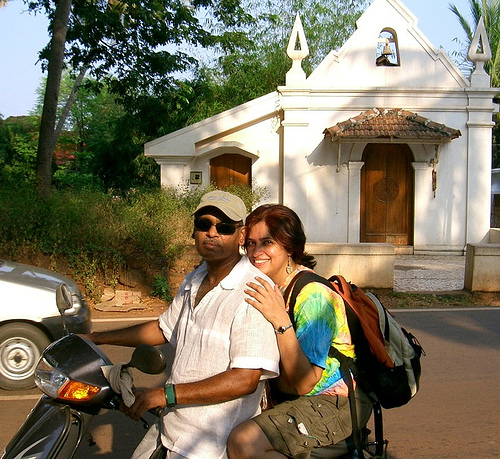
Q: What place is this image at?
A: It is at the church.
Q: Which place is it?
A: It is a church.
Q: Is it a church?
A: Yes, it is a church.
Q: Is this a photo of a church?
A: Yes, it is showing a church.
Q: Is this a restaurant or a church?
A: It is a church.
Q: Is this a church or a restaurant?
A: It is a church.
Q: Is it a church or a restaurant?
A: It is a church.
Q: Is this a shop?
A: No, it is a church.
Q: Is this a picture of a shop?
A: No, the picture is showing a church.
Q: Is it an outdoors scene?
A: Yes, it is outdoors.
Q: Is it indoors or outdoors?
A: It is outdoors.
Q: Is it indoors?
A: No, it is outdoors.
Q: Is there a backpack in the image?
A: Yes, there is a backpack.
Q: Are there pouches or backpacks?
A: Yes, there is a backpack.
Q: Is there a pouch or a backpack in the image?
A: Yes, there is a backpack.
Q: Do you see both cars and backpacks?
A: Yes, there are both a backpack and a car.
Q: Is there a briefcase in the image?
A: No, there are no briefcases.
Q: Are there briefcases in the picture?
A: No, there are no briefcases.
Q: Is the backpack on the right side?
A: Yes, the backpack is on the right of the image.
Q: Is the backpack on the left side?
A: No, the backpack is on the right of the image.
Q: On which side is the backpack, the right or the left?
A: The backpack is on the right of the image.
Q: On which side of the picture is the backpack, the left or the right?
A: The backpack is on the right of the image.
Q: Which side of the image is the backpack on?
A: The backpack is on the right of the image.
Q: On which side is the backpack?
A: The backpack is on the right of the image.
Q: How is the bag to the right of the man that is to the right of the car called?
A: The bag is a backpack.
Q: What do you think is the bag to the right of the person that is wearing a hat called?
A: The bag is a backpack.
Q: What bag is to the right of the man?
A: The bag is a backpack.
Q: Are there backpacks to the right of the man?
A: Yes, there is a backpack to the right of the man.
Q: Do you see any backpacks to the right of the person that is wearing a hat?
A: Yes, there is a backpack to the right of the man.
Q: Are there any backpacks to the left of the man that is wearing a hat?
A: No, the backpack is to the right of the man.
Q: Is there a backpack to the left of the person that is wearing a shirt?
A: No, the backpack is to the right of the man.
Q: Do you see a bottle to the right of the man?
A: No, there is a backpack to the right of the man.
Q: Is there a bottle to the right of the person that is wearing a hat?
A: No, there is a backpack to the right of the man.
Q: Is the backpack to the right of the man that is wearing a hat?
A: Yes, the backpack is to the right of the man.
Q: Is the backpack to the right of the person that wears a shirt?
A: Yes, the backpack is to the right of the man.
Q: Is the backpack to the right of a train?
A: No, the backpack is to the right of the man.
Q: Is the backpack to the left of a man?
A: No, the backpack is to the right of a man.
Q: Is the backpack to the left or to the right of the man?
A: The backpack is to the right of the man.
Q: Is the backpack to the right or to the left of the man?
A: The backpack is to the right of the man.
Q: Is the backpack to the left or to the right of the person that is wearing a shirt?
A: The backpack is to the right of the man.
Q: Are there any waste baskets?
A: No, there are no waste baskets.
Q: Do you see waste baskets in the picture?
A: No, there are no waste baskets.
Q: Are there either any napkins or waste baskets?
A: No, there are no waste baskets or napkins.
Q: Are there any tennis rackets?
A: No, there are no tennis rackets.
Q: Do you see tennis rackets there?
A: No, there are no tennis rackets.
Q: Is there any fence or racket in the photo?
A: No, there are no rackets or fences.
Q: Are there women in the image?
A: Yes, there is a woman.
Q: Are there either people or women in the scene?
A: Yes, there is a woman.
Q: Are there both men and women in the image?
A: Yes, there are both a woman and a man.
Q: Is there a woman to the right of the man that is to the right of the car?
A: Yes, there is a woman to the right of the man.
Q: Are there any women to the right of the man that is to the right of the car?
A: Yes, there is a woman to the right of the man.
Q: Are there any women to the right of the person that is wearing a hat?
A: Yes, there is a woman to the right of the man.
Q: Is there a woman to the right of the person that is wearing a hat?
A: Yes, there is a woman to the right of the man.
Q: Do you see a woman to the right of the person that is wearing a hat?
A: Yes, there is a woman to the right of the man.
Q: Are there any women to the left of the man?
A: No, the woman is to the right of the man.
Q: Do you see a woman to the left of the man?
A: No, the woman is to the right of the man.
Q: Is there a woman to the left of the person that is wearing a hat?
A: No, the woman is to the right of the man.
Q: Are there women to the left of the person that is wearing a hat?
A: No, the woman is to the right of the man.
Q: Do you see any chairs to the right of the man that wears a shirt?
A: No, there is a woman to the right of the man.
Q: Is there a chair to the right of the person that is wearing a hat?
A: No, there is a woman to the right of the man.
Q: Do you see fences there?
A: No, there are no fences.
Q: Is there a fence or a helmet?
A: No, there are no fences or helmets.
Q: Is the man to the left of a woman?
A: Yes, the man is to the left of a woman.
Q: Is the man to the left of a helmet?
A: No, the man is to the left of a woman.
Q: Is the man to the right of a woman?
A: No, the man is to the left of a woman.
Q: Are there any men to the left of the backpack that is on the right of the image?
A: Yes, there is a man to the left of the backpack.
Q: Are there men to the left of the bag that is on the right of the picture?
A: Yes, there is a man to the left of the backpack.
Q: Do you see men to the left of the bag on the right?
A: Yes, there is a man to the left of the backpack.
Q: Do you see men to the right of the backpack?
A: No, the man is to the left of the backpack.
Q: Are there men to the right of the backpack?
A: No, the man is to the left of the backpack.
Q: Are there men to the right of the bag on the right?
A: No, the man is to the left of the backpack.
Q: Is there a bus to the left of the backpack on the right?
A: No, there is a man to the left of the backpack.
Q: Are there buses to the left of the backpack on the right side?
A: No, there is a man to the left of the backpack.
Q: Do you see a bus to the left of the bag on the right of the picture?
A: No, there is a man to the left of the backpack.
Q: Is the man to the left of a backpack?
A: Yes, the man is to the left of a backpack.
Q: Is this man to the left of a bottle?
A: No, the man is to the left of a backpack.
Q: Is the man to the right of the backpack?
A: No, the man is to the left of the backpack.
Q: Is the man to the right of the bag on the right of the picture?
A: No, the man is to the left of the backpack.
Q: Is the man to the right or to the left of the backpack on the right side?
A: The man is to the left of the backpack.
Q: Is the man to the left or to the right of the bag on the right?
A: The man is to the left of the backpack.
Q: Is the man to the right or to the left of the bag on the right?
A: The man is to the left of the backpack.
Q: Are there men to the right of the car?
A: Yes, there is a man to the right of the car.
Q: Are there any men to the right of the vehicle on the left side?
A: Yes, there is a man to the right of the car.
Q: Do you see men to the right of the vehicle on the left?
A: Yes, there is a man to the right of the car.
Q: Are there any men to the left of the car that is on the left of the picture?
A: No, the man is to the right of the car.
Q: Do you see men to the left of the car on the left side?
A: No, the man is to the right of the car.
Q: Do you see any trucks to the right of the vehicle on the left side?
A: No, there is a man to the right of the car.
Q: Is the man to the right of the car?
A: Yes, the man is to the right of the car.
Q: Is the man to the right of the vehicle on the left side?
A: Yes, the man is to the right of the car.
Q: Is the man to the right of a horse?
A: No, the man is to the right of the car.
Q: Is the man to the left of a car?
A: No, the man is to the right of a car.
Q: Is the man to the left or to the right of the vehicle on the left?
A: The man is to the right of the car.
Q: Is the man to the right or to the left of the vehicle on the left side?
A: The man is to the right of the car.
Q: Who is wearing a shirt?
A: The man is wearing a shirt.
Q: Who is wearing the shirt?
A: The man is wearing a shirt.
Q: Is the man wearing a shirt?
A: Yes, the man is wearing a shirt.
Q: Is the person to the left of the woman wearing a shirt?
A: Yes, the man is wearing a shirt.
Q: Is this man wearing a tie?
A: No, the man is wearing a shirt.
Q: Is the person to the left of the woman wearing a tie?
A: No, the man is wearing a shirt.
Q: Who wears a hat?
A: The man wears a hat.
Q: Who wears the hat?
A: The man wears a hat.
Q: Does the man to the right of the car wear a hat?
A: Yes, the man wears a hat.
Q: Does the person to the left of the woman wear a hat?
A: Yes, the man wears a hat.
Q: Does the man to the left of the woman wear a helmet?
A: No, the man wears a hat.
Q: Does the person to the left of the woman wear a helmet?
A: No, the man wears a hat.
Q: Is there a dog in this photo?
A: No, there are no dogs.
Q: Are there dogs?
A: No, there are no dogs.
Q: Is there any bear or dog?
A: No, there are no dogs or bears.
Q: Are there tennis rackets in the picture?
A: No, there are no tennis rackets.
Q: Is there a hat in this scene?
A: Yes, there is a hat.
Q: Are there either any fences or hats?
A: Yes, there is a hat.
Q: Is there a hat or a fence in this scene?
A: Yes, there is a hat.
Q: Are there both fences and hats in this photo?
A: No, there is a hat but no fences.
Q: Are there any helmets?
A: No, there are no helmets.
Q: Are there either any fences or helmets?
A: No, there are no helmets or fences.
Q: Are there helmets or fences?
A: No, there are no helmets or fences.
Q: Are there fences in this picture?
A: No, there are no fences.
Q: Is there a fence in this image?
A: No, there are no fences.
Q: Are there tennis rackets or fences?
A: No, there are no fences or tennis rackets.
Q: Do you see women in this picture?
A: Yes, there is a woman.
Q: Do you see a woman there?
A: Yes, there is a woman.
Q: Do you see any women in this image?
A: Yes, there is a woman.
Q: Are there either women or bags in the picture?
A: Yes, there is a woman.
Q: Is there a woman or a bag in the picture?
A: Yes, there is a woman.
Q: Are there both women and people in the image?
A: Yes, there are both a woman and a person.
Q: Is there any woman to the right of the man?
A: Yes, there is a woman to the right of the man.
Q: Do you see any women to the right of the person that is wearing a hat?
A: Yes, there is a woman to the right of the man.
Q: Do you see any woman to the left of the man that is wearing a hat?
A: No, the woman is to the right of the man.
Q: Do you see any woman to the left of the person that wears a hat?
A: No, the woman is to the right of the man.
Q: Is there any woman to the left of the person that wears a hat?
A: No, the woman is to the right of the man.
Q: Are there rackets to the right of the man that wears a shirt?
A: No, there is a woman to the right of the man.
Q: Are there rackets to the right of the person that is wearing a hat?
A: No, there is a woman to the right of the man.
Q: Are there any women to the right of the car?
A: Yes, there is a woman to the right of the car.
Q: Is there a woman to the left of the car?
A: No, the woman is to the right of the car.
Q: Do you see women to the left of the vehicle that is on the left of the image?
A: No, the woman is to the right of the car.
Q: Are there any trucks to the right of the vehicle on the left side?
A: No, there is a woman to the right of the car.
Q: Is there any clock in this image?
A: No, there are no clocks.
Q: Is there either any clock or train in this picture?
A: No, there are no clocks or trains.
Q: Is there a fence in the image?
A: No, there are no fences.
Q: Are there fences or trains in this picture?
A: No, there are no fences or trains.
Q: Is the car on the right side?
A: No, the car is on the left of the image.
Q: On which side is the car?
A: The car is on the left of the image.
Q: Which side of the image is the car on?
A: The car is on the left of the image.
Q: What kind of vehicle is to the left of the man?
A: The vehicle is a car.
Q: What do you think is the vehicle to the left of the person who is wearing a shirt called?
A: The vehicle is a car.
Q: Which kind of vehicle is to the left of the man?
A: The vehicle is a car.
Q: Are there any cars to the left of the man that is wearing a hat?
A: Yes, there is a car to the left of the man.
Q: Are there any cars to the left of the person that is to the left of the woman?
A: Yes, there is a car to the left of the man.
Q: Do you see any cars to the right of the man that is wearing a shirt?
A: No, the car is to the left of the man.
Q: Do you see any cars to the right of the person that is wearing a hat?
A: No, the car is to the left of the man.